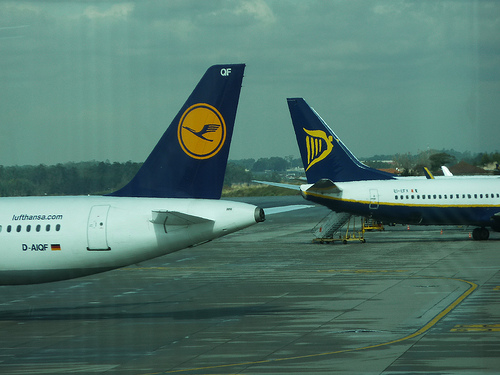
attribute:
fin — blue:
[117, 51, 247, 202]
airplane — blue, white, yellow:
[243, 69, 497, 274]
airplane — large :
[1, 189, 237, 281]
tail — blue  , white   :
[287, 95, 397, 179]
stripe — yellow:
[303, 190, 499, 207]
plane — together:
[251, 97, 496, 241]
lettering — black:
[8, 211, 65, 225]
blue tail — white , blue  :
[112, 59, 248, 200]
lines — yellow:
[413, 312, 440, 340]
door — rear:
[75, 195, 113, 256]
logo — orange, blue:
[178, 104, 225, 159]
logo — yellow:
[299, 123, 333, 171]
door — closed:
[84, 204, 112, 254]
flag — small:
[49, 242, 59, 252]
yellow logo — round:
[176, 103, 227, 158]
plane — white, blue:
[2, 63, 264, 285]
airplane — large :
[272, 88, 498, 248]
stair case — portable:
[307, 210, 349, 240]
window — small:
[54, 218, 67, 240]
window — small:
[9, 219, 26, 238]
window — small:
[24, 219, 34, 234]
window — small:
[31, 221, 48, 238]